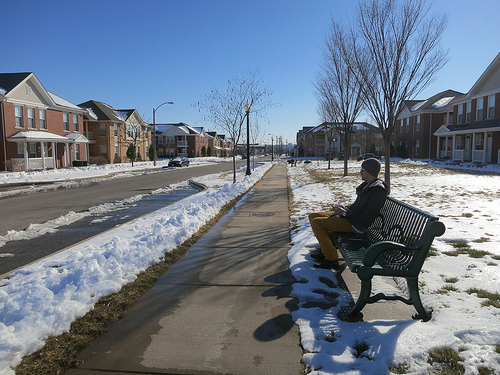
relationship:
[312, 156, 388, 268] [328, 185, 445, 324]
man on bench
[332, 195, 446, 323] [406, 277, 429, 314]
bench has leg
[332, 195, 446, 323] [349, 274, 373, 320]
bench has leg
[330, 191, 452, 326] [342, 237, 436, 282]
bench has armrest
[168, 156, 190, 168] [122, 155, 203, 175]
car on curb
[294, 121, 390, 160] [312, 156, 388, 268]
house behind man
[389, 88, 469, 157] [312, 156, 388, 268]
brick house behind man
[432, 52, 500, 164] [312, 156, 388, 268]
brick house behind man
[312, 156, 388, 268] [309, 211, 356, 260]
man wears pants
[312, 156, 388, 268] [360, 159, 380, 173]
man wears hat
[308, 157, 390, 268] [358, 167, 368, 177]
man wears sunglasses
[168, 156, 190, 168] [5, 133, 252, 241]
car on street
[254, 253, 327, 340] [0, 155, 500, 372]
black shadow on ground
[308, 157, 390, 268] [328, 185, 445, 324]
man on bench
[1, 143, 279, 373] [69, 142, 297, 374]
grass next to sidewalk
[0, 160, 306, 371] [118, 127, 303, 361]
sidewalk left of sidewalk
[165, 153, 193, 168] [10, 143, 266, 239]
car on street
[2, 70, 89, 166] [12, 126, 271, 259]
brick house left of street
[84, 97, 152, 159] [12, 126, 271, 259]
brick house left of street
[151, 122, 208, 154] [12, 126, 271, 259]
brick house left of street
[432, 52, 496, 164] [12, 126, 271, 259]
brick house left of street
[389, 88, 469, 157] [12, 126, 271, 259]
brick house left of street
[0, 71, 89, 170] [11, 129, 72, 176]
brick house has porch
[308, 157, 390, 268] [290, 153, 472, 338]
man on bench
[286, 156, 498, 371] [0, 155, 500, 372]
snow on ground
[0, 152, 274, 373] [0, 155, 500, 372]
snow on ground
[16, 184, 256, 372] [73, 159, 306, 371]
grass by sidewalk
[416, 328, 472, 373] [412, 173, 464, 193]
grass growing through snow